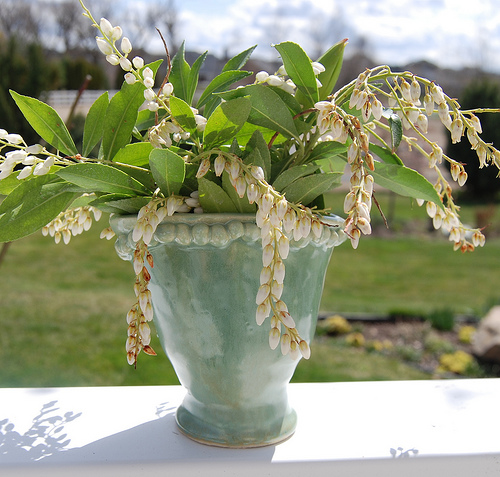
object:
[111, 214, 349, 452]
vase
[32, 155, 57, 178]
flower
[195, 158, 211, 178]
pod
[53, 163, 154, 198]
leaf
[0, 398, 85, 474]
shadow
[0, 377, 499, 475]
ledge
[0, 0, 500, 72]
sky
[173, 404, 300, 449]
base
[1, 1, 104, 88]
tree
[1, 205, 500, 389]
yard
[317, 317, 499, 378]
garden